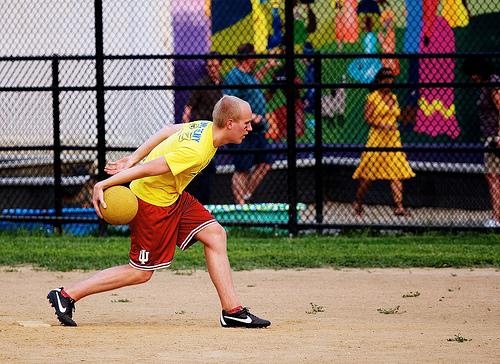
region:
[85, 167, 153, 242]
yellow kickball in the boy's hand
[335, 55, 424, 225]
woman wearing a yellow dress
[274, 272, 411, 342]
dirt in the field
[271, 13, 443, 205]
black fence around the field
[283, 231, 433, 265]
grass along the side of the field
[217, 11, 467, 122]
painting on the wall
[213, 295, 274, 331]
black and white cleat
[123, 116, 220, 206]
yellow t-shirt on the boy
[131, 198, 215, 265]
boy is wearing burgundy shorts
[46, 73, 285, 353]
boy is pitching the ball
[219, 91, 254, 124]
boy has short hair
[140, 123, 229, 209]
yellow and blue shirt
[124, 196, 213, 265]
red and white shorts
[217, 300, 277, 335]
black and white shoes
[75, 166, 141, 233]
boy rolls yellow kickball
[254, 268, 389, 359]
dirt is light brown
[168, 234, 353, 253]
green grass behind boy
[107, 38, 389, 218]
black fence behind boy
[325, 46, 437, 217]
woman has yellow dress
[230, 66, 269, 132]
man has blue shirt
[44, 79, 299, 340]
this is a person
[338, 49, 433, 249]
this is a person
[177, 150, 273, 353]
the leg of a boy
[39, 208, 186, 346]
the leg of a boy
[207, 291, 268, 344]
this is a shoe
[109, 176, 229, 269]
these are red shorts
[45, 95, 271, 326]
the man with a ball in his hand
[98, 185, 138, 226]
the yellow ball in the man's hand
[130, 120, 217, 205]
the short sleeved yellow shirt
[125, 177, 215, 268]
the red shorts on the man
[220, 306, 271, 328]
the shoe on the man's foot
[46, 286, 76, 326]
the shoe on the man's foot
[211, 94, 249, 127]
the hair on the man's head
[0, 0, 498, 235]
the black fence near the man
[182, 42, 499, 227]
the people on the other side of the fence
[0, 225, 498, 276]
the grass near the fence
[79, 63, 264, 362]
person playing kickball outside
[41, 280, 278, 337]
person wearing Nike shoes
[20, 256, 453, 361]
dirt on playing field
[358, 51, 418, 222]
woman in yellow dress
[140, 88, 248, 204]
player wearing yellow shirt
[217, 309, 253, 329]
Nike logo on shoe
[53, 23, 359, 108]
wire fence surrounding field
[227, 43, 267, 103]
man looking at mural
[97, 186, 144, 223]
A round yellow ball.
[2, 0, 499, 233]
A black chainlink fence.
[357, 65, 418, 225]
A person wearing a yellow dress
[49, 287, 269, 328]
A pair of black and white nike cleats.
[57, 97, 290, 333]
a guy about to underhandedly throw a round ball.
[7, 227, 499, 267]
A grassy patch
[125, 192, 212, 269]
A pair of red and white sports shorts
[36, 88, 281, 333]
kid throwing a dodgeball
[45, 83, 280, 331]
kid throwing a dodgeball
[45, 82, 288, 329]
kid throwing a dodgeball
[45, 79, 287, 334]
kid throwing a dodgeball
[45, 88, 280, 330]
kid throwing a dodgeball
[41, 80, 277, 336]
kid throwing a dodgeball